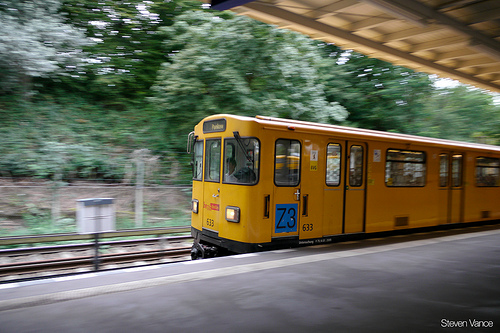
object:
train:
[183, 113, 500, 261]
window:
[271, 137, 302, 187]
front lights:
[189, 199, 241, 225]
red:
[205, 203, 222, 211]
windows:
[190, 140, 266, 185]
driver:
[224, 158, 240, 182]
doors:
[320, 139, 368, 235]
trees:
[151, 13, 350, 188]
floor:
[0, 228, 500, 332]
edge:
[188, 224, 250, 254]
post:
[94, 235, 103, 270]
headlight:
[225, 205, 241, 223]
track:
[0, 233, 197, 270]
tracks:
[0, 224, 192, 282]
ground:
[0, 264, 500, 332]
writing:
[438, 318, 495, 331]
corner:
[415, 320, 436, 331]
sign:
[73, 197, 115, 237]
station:
[0, 0, 500, 331]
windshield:
[192, 169, 253, 187]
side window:
[385, 147, 427, 186]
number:
[299, 219, 317, 231]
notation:
[274, 201, 298, 232]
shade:
[258, 0, 500, 50]